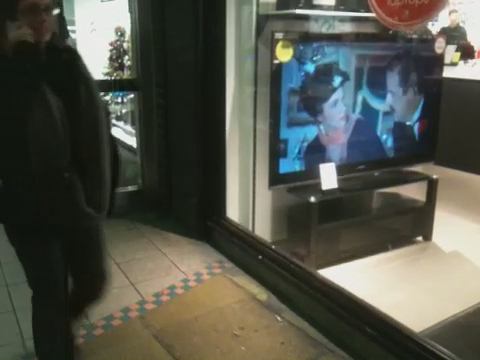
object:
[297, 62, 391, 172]
mary poppins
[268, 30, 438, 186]
tv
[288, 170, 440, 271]
cabinet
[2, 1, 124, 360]
person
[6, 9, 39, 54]
phone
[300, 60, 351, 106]
black hat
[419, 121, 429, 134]
red rose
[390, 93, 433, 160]
lapel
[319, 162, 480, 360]
floor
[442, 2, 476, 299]
store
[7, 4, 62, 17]
eyeglasses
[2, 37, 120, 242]
jacket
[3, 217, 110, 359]
pants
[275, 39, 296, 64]
yellow circle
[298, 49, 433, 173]
woman and man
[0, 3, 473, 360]
room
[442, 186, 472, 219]
tiles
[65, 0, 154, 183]
window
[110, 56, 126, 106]
person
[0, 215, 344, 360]
floor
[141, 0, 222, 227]
entrance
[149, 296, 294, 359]
tile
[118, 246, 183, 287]
tile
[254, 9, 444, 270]
display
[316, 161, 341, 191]
price tag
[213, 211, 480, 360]
molding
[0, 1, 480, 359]
building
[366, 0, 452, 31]
advertising sticker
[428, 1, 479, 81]
window